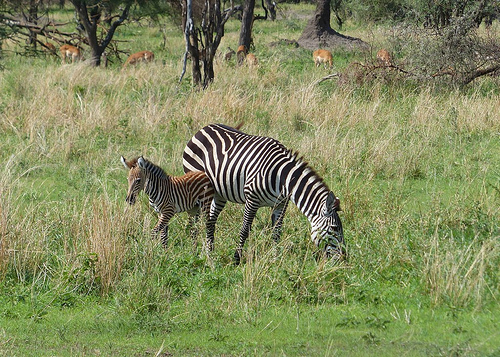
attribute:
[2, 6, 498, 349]
grass — grassy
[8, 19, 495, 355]
landscape — green